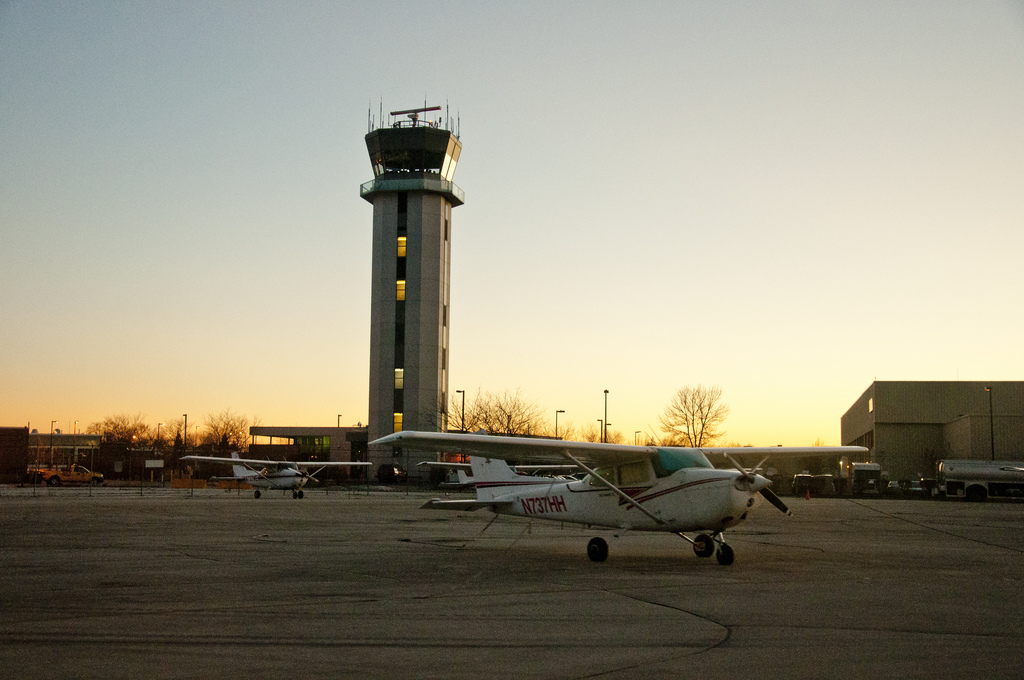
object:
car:
[27, 463, 103, 484]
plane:
[179, 452, 372, 499]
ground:
[0, 487, 1023, 680]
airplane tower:
[360, 89, 464, 483]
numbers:
[521, 495, 567, 514]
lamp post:
[455, 390, 464, 433]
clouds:
[476, 27, 899, 294]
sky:
[0, 0, 1024, 455]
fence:
[141, 460, 248, 497]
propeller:
[724, 452, 794, 517]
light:
[604, 390, 612, 443]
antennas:
[368, 90, 460, 138]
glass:
[397, 237, 406, 257]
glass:
[395, 369, 404, 389]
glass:
[651, 448, 713, 478]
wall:
[365, 126, 451, 168]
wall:
[366, 193, 438, 444]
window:
[617, 460, 650, 486]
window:
[589, 466, 615, 486]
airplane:
[368, 428, 869, 565]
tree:
[660, 383, 730, 448]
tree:
[446, 386, 547, 438]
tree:
[195, 406, 262, 452]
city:
[0, 91, 1024, 495]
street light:
[597, 419, 603, 443]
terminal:
[0, 369, 1021, 449]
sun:
[220, 362, 871, 450]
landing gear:
[716, 543, 734, 565]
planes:
[180, 429, 869, 566]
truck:
[51, 447, 54, 468]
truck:
[939, 459, 1024, 498]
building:
[841, 381, 1024, 495]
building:
[650, 445, 869, 495]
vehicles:
[764, 462, 926, 497]